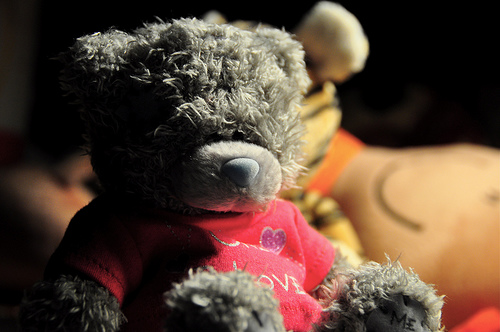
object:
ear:
[259, 26, 313, 95]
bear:
[18, 12, 449, 331]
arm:
[280, 209, 360, 310]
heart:
[257, 225, 290, 257]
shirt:
[49, 183, 344, 330]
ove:
[253, 267, 307, 301]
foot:
[313, 252, 446, 330]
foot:
[156, 260, 291, 331]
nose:
[218, 152, 261, 186]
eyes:
[257, 84, 276, 110]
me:
[387, 308, 416, 331]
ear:
[293, 1, 373, 84]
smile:
[369, 157, 423, 234]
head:
[54, 10, 316, 222]